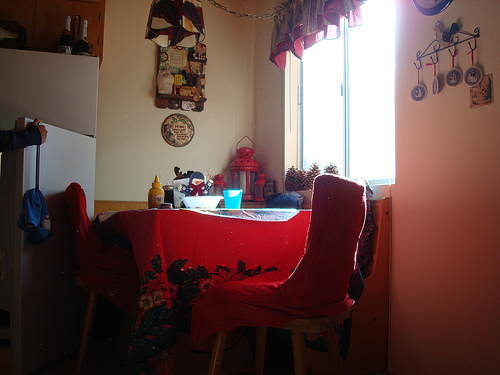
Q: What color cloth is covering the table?
A: Red.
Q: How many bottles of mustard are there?
A: 1.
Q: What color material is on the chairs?
A: Red.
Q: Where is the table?
A: Between the refrigerator and the window.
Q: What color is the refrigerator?
A: White.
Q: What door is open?
A: The refrigerator door.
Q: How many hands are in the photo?
A: 1.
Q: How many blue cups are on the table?
A: 1.